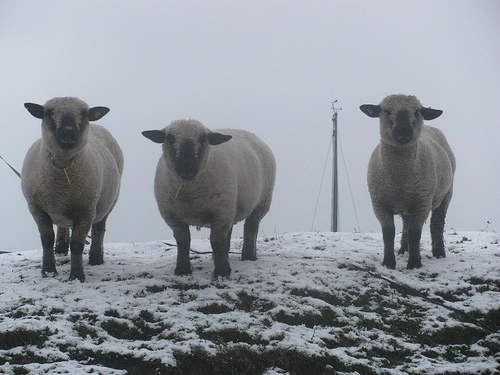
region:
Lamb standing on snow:
[356, 93, 460, 272]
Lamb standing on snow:
[139, 118, 279, 280]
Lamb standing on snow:
[18, 93, 125, 283]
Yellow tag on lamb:
[61, 165, 71, 186]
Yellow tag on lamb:
[170, 179, 184, 198]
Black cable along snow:
[151, 238, 496, 336]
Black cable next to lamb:
[162, 239, 498, 334]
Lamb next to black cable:
[353, 92, 458, 269]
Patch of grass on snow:
[100, 317, 160, 342]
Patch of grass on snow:
[267, 303, 353, 332]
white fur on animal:
[68, 210, 80, 213]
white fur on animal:
[403, 195, 426, 197]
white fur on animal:
[395, 169, 413, 174]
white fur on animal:
[219, 176, 236, 188]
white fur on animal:
[96, 153, 121, 182]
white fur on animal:
[181, 131, 198, 137]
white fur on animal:
[388, 98, 409, 113]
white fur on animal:
[418, 157, 459, 184]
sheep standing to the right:
[356, 85, 458, 287]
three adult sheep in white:
[5, 67, 479, 295]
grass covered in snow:
[16, 274, 319, 345]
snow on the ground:
[5, 271, 313, 367]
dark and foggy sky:
[7, 3, 397, 90]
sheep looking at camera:
[135, 103, 226, 177]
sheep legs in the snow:
[370, 198, 429, 279]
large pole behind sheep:
[321, 89, 361, 262]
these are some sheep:
[20, 100, 360, 247]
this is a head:
[139, 109, 235, 172]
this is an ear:
[142, 128, 164, 175]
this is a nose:
[168, 156, 190, 169]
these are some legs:
[151, 226, 290, 296]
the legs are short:
[158, 238, 319, 276]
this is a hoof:
[183, 249, 229, 266]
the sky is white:
[196, 38, 312, 128]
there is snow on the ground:
[233, 261, 373, 369]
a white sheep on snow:
[345, 85, 480, 280]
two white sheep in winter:
[142, 65, 473, 301]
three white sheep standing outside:
[20, 61, 470, 303]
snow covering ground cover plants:
[230, 270, 492, 371]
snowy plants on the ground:
[160, 291, 431, 371]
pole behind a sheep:
[310, 65, 475, 270]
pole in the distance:
[285, 90, 365, 265]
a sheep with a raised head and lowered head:
[140, 87, 470, 292]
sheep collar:
[32, 135, 98, 195]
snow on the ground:
[271, 215, 368, 300]